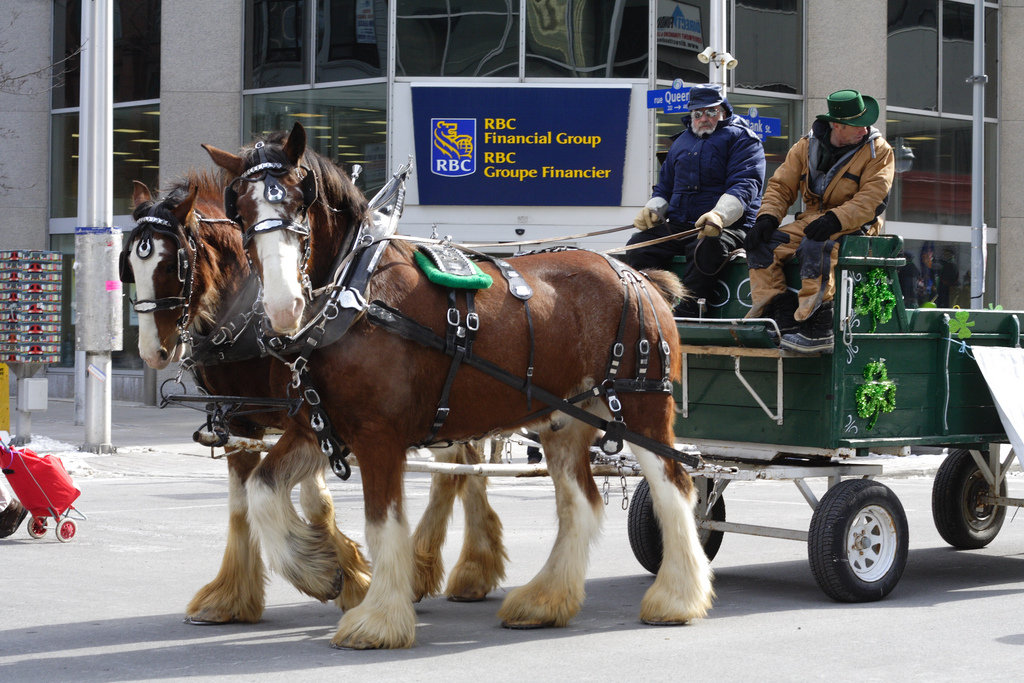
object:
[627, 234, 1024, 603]
wagon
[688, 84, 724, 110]
hat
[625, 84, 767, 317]
man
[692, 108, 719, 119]
sunglasses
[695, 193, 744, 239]
gloves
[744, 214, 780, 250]
gloves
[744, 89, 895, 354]
man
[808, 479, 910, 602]
wheel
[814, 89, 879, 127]
hat